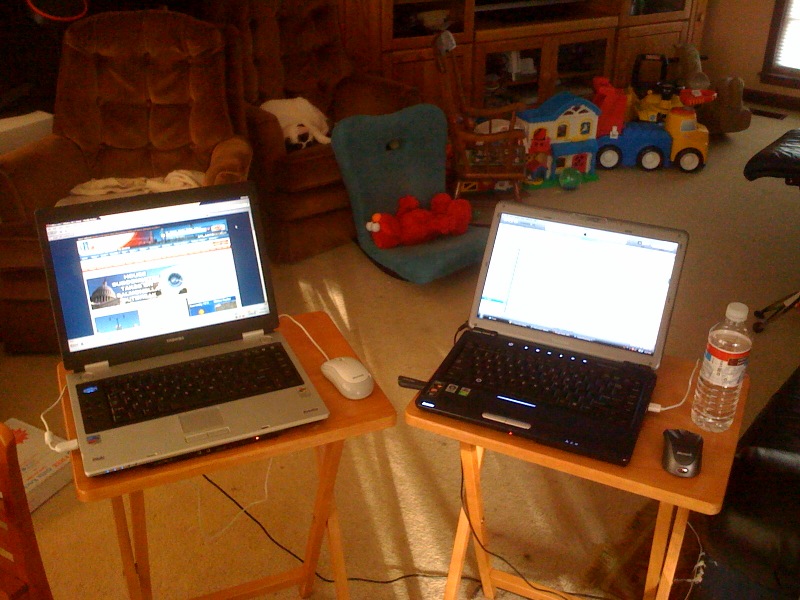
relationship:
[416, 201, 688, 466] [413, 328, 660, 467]
laptop with keyboard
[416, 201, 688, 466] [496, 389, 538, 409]
laptop with light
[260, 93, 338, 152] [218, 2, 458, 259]
cat sleeping in chair